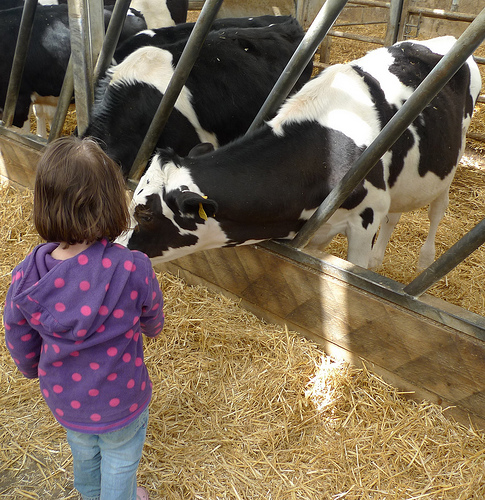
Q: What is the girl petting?
A: A cow.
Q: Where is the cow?
A: In the pen.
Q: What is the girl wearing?
A: A purple and pink polka dot hoodie.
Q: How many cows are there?
A: Three.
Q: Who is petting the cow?
A: A child.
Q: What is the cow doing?
A: Sniffing the girl.